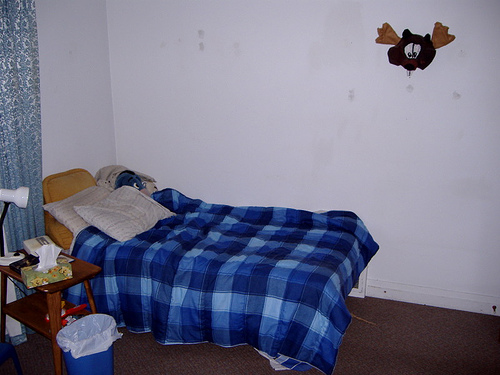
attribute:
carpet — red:
[27, 280, 493, 373]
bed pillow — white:
[52, 167, 178, 257]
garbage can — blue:
[58, 312, 115, 372]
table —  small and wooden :
[3, 232, 103, 372]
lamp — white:
[0, 179, 41, 265]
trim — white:
[367, 277, 499, 318]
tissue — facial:
[32, 241, 63, 273]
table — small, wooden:
[1, 248, 100, 373]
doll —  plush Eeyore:
[109, 165, 156, 199]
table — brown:
[21, 263, 143, 347]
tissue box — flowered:
[18, 263, 71, 289]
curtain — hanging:
[3, 0, 51, 261]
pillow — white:
[71, 180, 177, 243]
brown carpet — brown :
[8, 292, 495, 373]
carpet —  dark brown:
[379, 332, 444, 358]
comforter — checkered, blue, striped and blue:
[63, 186, 381, 373]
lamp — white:
[2, 187, 27, 265]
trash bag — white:
[55, 312, 122, 358]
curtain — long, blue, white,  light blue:
[2, 0, 47, 346]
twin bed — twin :
[44, 161, 381, 373]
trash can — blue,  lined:
[53, 312, 125, 364]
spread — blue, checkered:
[62, 185, 391, 374]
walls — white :
[31, 3, 497, 307]